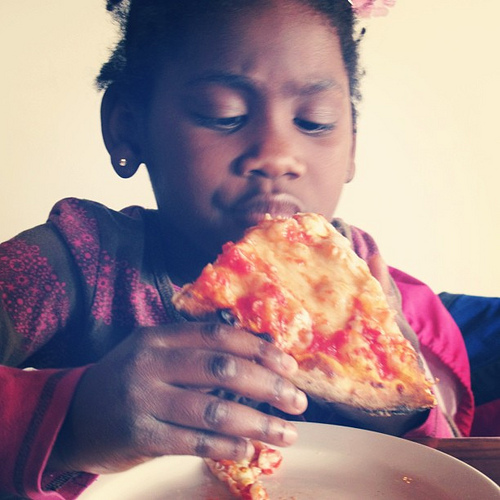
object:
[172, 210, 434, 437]
pizza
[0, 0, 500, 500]
child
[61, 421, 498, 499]
plate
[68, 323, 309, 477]
hand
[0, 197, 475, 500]
sweater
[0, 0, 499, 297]
wall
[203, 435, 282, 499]
chunk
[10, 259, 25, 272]
flower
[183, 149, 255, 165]
eyebrown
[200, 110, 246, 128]
eye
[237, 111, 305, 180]
nose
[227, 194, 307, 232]
lips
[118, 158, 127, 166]
earring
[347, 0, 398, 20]
bow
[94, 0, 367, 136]
hair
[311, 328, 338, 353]
tomatos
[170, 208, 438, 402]
cheese